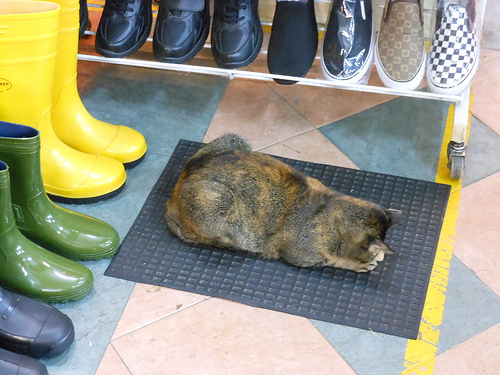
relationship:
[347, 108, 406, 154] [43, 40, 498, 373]
tile on floor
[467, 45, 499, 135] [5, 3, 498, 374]
tile on floor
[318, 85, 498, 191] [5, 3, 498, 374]
black tile on floor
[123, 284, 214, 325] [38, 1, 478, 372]
tile on floor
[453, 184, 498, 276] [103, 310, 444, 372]
red tile on floor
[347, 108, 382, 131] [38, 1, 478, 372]
tile on floor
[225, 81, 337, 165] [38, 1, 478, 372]
tile on floor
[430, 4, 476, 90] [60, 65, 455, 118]
checkered shoe on shoe rack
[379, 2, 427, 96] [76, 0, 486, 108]
shoe on shoe rack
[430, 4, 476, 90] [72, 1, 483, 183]
checkered shoe on shoe rack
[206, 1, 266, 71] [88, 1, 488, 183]
shoe on rack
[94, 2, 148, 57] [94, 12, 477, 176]
shoe on shoe rack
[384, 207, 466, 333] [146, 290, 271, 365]
mat on floor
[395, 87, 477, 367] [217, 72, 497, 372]
yellow stripe on floor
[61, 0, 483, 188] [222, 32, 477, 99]
rack for shoes